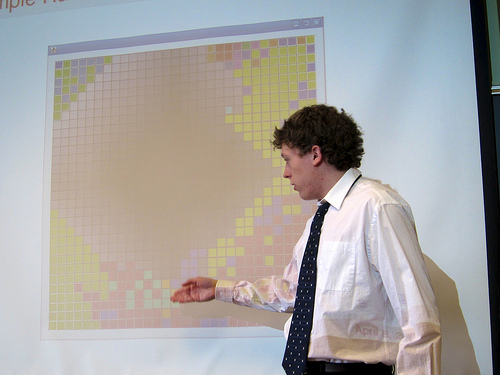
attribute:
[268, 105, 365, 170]
hair — brown, messy, dark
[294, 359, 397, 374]
belt — black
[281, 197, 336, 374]
tie — dark, black, navy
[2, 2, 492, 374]
white board — large, yellow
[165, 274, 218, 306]
hand — stretched out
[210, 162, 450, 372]
shirt — white, big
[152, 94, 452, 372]
teacher — dorky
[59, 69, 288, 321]
picture — yellow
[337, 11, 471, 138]
wall — white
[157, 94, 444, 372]
man — pointing, standing, working, presenting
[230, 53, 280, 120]
picture — squared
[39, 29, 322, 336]
pixels — orange